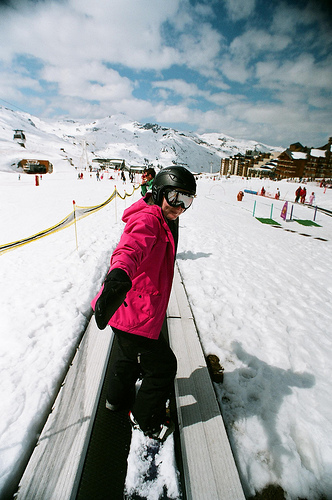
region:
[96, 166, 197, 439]
A woman snowboarding on snow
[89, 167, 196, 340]
Woman wearing a pink jacket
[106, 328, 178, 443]
Woman wearing black pants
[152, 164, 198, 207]
Woman wearing a black helmet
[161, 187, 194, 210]
Woman wearing black googles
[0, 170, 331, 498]
Ground covered with snow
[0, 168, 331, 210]
People playing on snow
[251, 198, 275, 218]
Blue poles on snow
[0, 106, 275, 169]
Mountains covered with snow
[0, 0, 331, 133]
White clouds on the sky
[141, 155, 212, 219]
head of a person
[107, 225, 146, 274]
arm of a person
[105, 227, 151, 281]
an arm of a person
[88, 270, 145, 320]
hand of a person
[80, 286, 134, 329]
a hand of a person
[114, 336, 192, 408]
leg of a person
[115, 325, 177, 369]
thigh of a person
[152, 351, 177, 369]
knee of a person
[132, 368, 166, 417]
leg of a person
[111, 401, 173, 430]
feet of a person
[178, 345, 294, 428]
the shadow is on the ground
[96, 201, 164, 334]
the jacket is pink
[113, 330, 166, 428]
the pant is black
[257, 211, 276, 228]
the object is green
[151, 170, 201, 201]
the helmet is black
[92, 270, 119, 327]
the glove is black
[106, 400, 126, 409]
the shoe is white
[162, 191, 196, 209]
the gogoes are blck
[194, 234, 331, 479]
the ground is coverd with the snow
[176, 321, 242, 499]
the wood is white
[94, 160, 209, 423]
this is a lady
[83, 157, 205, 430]
the lady is skating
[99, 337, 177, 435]
these are the legs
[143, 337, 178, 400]
this is the knee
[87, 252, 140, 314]
this is the hand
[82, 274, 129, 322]
this is a glove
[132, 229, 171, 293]
this is the jacket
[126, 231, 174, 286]
the jacket is warm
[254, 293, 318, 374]
this is the snow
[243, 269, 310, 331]
the snow is white in color